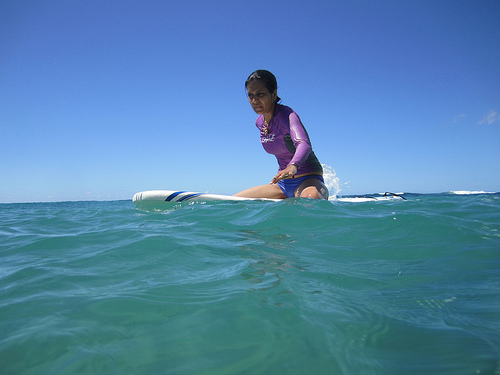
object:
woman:
[229, 68, 328, 201]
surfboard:
[131, 189, 401, 202]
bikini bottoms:
[272, 170, 323, 200]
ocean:
[0, 189, 498, 374]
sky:
[1, 0, 499, 204]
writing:
[258, 132, 277, 145]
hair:
[245, 69, 280, 104]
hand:
[271, 162, 298, 184]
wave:
[222, 197, 355, 226]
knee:
[300, 189, 324, 201]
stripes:
[164, 188, 187, 202]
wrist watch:
[287, 161, 301, 166]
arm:
[286, 112, 313, 167]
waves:
[348, 211, 486, 242]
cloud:
[459, 109, 498, 128]